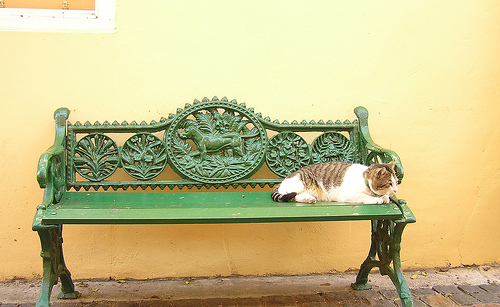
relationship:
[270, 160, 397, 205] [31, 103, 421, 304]
cat laying on bench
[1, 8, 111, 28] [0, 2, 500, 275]
window sill on wall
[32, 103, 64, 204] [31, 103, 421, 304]
armrest of bench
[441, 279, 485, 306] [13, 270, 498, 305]
brick attached to sidewalk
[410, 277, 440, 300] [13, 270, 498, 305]
brick attached to sidewalk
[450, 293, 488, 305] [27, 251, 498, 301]
brick attached to sidewalk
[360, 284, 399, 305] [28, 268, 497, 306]
brick attached to sidewalk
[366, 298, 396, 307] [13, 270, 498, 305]
brick attached to sidewalk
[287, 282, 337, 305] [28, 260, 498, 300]
brick attached to sidewalk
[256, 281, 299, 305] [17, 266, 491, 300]
brick attached to sidewalk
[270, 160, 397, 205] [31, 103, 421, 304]
cat sitting on bench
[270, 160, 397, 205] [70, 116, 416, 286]
cat sitting on bench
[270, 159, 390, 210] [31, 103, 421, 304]
cat sitting on bench